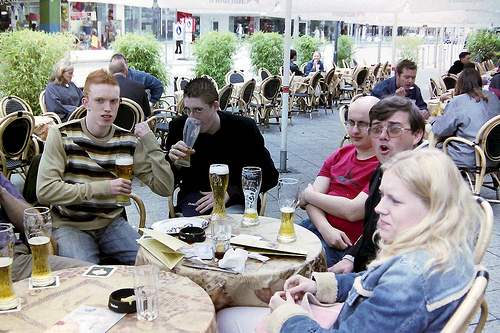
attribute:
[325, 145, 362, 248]
shirt — red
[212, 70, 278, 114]
chairs — wooden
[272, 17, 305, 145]
pole — white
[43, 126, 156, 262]
sweater — stripes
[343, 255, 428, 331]
jacket — denim